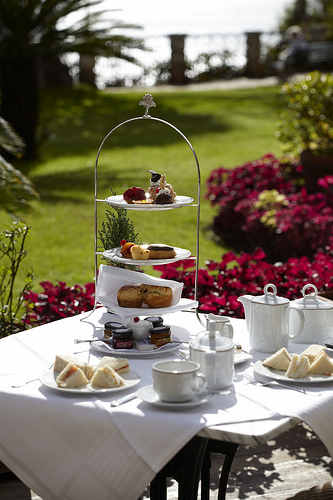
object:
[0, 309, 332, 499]
table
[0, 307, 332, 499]
tablecloth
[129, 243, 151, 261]
pastries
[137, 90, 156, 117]
silver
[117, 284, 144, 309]
pastries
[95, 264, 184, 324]
napkin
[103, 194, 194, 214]
platter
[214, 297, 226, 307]
flowers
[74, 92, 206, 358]
pastry display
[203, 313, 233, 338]
creamer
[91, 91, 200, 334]
stand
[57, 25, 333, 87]
fence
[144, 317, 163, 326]
jar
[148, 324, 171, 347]
jar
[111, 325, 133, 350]
jar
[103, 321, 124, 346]
jar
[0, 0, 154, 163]
tree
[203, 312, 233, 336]
server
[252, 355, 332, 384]
plate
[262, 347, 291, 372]
sandwich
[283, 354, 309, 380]
sandwich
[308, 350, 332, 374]
sandwich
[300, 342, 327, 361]
sandwich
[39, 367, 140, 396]
plate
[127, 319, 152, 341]
container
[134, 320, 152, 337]
butter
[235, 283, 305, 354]
pot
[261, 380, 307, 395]
fork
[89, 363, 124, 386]
sandwich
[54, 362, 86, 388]
sandwich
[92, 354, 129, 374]
sandwich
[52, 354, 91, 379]
sandwich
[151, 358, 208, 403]
cup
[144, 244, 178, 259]
pastries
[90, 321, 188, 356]
shelf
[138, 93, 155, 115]
decorative piece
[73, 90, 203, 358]
tray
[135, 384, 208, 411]
saucer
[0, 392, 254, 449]
table edge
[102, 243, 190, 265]
platter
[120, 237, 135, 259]
pastries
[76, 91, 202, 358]
rack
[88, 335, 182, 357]
plate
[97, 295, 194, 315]
plate